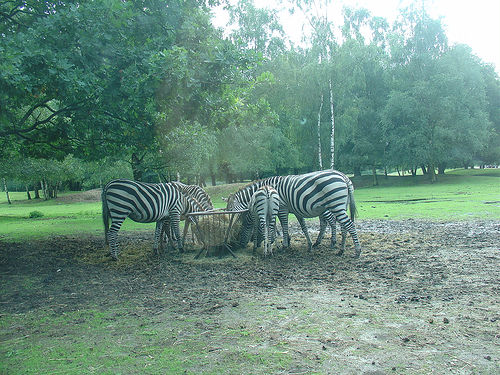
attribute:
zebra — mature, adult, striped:
[100, 179, 211, 263]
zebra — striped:
[221, 168, 363, 259]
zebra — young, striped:
[236, 183, 281, 258]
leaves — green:
[0, 1, 240, 164]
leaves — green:
[383, 42, 499, 165]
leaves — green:
[200, 32, 289, 182]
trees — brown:
[2, 171, 63, 207]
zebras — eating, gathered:
[101, 166, 365, 260]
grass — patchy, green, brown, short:
[2, 170, 500, 374]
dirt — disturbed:
[4, 219, 499, 342]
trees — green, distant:
[162, 2, 499, 182]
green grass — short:
[2, 167, 497, 236]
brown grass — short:
[0, 217, 495, 375]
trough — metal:
[187, 207, 252, 259]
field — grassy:
[3, 168, 499, 237]